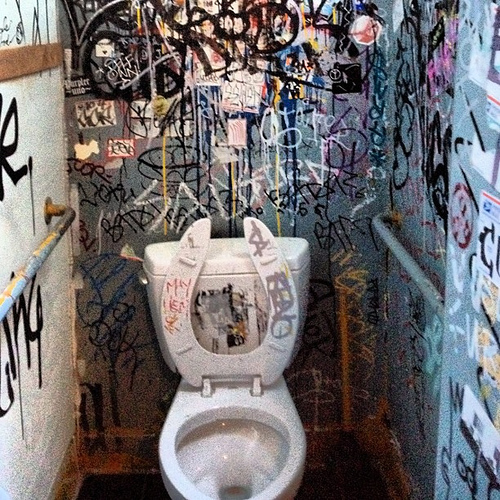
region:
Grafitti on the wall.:
[109, 17, 375, 186]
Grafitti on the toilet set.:
[158, 253, 313, 370]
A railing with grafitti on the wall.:
[13, 214, 93, 307]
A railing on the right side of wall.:
[371, 214, 469, 328]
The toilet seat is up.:
[157, 244, 292, 373]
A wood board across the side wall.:
[12, 44, 79, 86]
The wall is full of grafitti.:
[95, 15, 412, 151]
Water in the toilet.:
[214, 460, 254, 499]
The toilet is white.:
[133, 393, 308, 497]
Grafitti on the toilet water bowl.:
[194, 279, 273, 346]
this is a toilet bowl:
[186, 431, 281, 498]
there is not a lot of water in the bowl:
[192, 448, 277, 497]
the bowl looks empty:
[176, 418, 291, 495]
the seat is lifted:
[157, 210, 307, 395]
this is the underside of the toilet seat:
[155, 204, 308, 396]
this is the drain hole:
[217, 478, 248, 499]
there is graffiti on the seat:
[147, 200, 319, 400]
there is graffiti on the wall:
[61, 5, 392, 224]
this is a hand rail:
[365, 207, 460, 343]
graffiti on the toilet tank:
[199, 283, 281, 343]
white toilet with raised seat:
[135, 216, 315, 498]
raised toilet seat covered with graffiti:
[157, 215, 301, 396]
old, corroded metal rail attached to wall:
[1, 196, 77, 318]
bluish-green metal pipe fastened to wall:
[367, 203, 447, 327]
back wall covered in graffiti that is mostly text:
[57, 0, 389, 430]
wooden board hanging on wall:
[1, 40, 63, 82]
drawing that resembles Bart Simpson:
[438, 373, 480, 498]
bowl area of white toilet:
[173, 404, 293, 498]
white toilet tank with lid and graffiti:
[140, 234, 310, 383]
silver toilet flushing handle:
[134, 266, 149, 286]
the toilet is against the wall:
[140, 231, 313, 497]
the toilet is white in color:
[136, 232, 312, 496]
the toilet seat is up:
[156, 220, 296, 387]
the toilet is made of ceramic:
[142, 236, 311, 498]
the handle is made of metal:
[136, 272, 148, 289]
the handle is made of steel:
[135, 268, 151, 287]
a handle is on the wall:
[0, 197, 80, 352]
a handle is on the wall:
[370, 203, 470, 349]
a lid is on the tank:
[145, 238, 308, 273]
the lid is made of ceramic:
[142, 230, 311, 278]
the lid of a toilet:
[180, 225, 291, 373]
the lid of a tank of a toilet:
[152, 238, 290, 275]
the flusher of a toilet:
[130, 262, 147, 293]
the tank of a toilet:
[141, 275, 296, 372]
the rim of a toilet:
[142, 426, 195, 468]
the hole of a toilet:
[220, 471, 248, 498]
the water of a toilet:
[186, 455, 268, 497]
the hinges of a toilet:
[189, 365, 261, 399]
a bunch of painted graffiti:
[141, 75, 292, 205]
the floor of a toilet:
[90, 465, 132, 498]